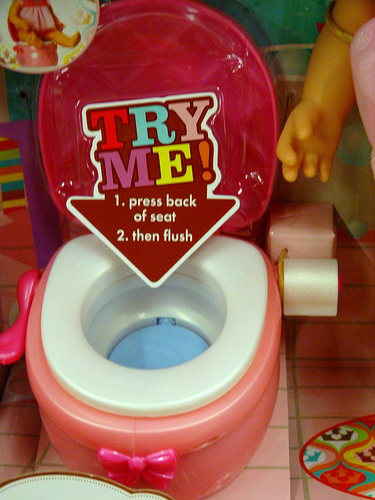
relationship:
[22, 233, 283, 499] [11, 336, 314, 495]
toilet on shelf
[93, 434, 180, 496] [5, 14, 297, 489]
bow on toilet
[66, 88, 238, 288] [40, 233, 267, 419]
arrow on bowl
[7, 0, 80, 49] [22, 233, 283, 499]
bear picture on toilet